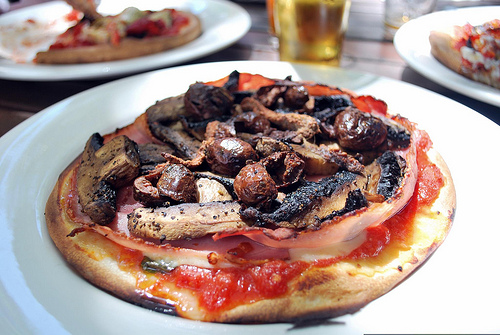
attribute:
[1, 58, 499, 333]
plate — white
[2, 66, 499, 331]
white plate — crisp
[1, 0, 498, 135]
table — brown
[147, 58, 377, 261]
meat balls — tasty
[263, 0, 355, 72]
mug — filled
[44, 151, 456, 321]
crust — brown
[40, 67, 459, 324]
pizza — decorated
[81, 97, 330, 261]
meat — brown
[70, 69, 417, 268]
pizza toppings — burnt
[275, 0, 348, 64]
glass — drinking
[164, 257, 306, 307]
pizza patch — red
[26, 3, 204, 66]
pizza — half eaten